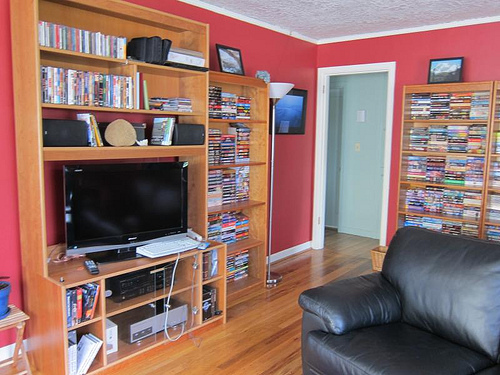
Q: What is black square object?
A: Tv.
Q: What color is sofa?
A: Black.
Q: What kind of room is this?
A: Living room.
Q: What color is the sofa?
A: Black.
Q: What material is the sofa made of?
A: Leather.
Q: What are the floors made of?
A: Wood.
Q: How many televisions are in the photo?
A: One.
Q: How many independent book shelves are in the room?
A: Three.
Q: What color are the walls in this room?
A: Coral.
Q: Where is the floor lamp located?
A: Next to the bookshelf close to the door.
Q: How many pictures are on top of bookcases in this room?
A: Two.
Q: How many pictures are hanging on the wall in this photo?
A: One.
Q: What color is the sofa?
A: Black.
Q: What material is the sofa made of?
A: Leather.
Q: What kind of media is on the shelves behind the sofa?
A: Dvd's.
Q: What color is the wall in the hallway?
A: Pastel green.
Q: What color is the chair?
A: Gray.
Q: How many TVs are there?
A: 1.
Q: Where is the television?
A: On the shelf.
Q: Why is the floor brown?
A: It's wood.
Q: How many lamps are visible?
A: 1.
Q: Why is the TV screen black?
A: It's turned off.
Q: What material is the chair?
A: Leather.